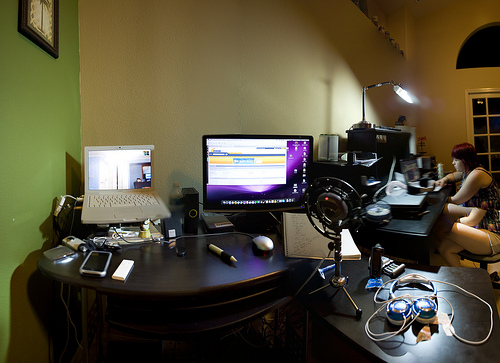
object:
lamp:
[357, 80, 419, 130]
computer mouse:
[252, 236, 275, 251]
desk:
[53, 191, 320, 346]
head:
[450, 142, 473, 172]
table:
[35, 211, 292, 361]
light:
[390, 83, 413, 104]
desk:
[24, 222, 496, 358]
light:
[358, 80, 415, 126]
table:
[40, 234, 295, 305]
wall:
[119, 19, 334, 124]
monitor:
[203, 134, 313, 214]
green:
[26, 80, 71, 125]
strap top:
[454, 165, 499, 237]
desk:
[32, 210, 390, 302]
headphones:
[386, 278, 446, 340]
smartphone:
[76, 246, 116, 281]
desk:
[119, 234, 280, 305]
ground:
[390, 93, 452, 167]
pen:
[206, 239, 236, 265]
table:
[25, 210, 317, 357]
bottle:
[167, 182, 183, 212]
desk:
[55, 208, 269, 314]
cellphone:
[80, 250, 113, 277]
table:
[130, 242, 282, 291]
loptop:
[395, 155, 440, 191]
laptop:
[78, 144, 170, 224]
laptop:
[401, 153, 442, 200]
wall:
[2, 0, 79, 362]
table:
[37, 210, 326, 292]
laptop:
[80, 140, 177, 231]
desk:
[34, 168, 464, 347]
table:
[33, 200, 360, 340]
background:
[0, 0, 500, 153]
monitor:
[199, 135, 317, 227]